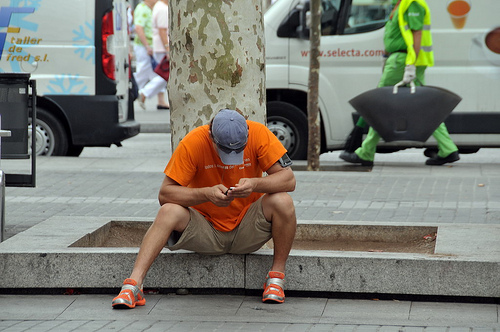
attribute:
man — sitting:
[111, 108, 297, 309]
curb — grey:
[0, 215, 499, 304]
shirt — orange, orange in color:
[163, 120, 288, 232]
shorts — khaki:
[163, 192, 272, 256]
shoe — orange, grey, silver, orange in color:
[111, 277, 146, 309]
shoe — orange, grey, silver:
[262, 268, 286, 303]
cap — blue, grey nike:
[211, 109, 247, 165]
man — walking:
[339, 0, 460, 166]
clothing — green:
[353, 0, 458, 161]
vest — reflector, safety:
[398, 0, 434, 67]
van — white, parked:
[263, 0, 499, 160]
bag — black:
[348, 77, 463, 144]